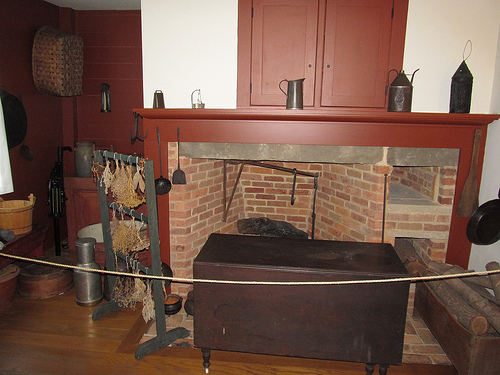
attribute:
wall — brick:
[189, 150, 387, 253]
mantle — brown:
[127, 101, 498, 301]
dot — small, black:
[306, 58, 314, 71]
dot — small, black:
[323, 60, 335, 70]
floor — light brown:
[0, 289, 458, 370]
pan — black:
[466, 190, 498, 245]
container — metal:
[277, 81, 321, 128]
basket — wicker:
[34, 31, 86, 99]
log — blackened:
[232, 219, 300, 235]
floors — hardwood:
[23, 317, 107, 352]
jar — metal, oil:
[383, 60, 435, 129]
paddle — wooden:
[466, 130, 498, 249]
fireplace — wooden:
[119, 115, 459, 293]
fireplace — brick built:
[145, 136, 445, 289]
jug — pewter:
[265, 65, 333, 122]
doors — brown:
[246, 13, 396, 109]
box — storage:
[189, 229, 413, 366]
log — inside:
[225, 208, 317, 254]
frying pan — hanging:
[461, 194, 496, 244]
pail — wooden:
[0, 202, 51, 229]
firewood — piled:
[412, 256, 497, 343]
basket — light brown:
[1, 185, 42, 221]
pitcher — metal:
[278, 72, 308, 108]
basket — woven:
[27, 21, 87, 101]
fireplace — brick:
[130, 103, 499, 365]